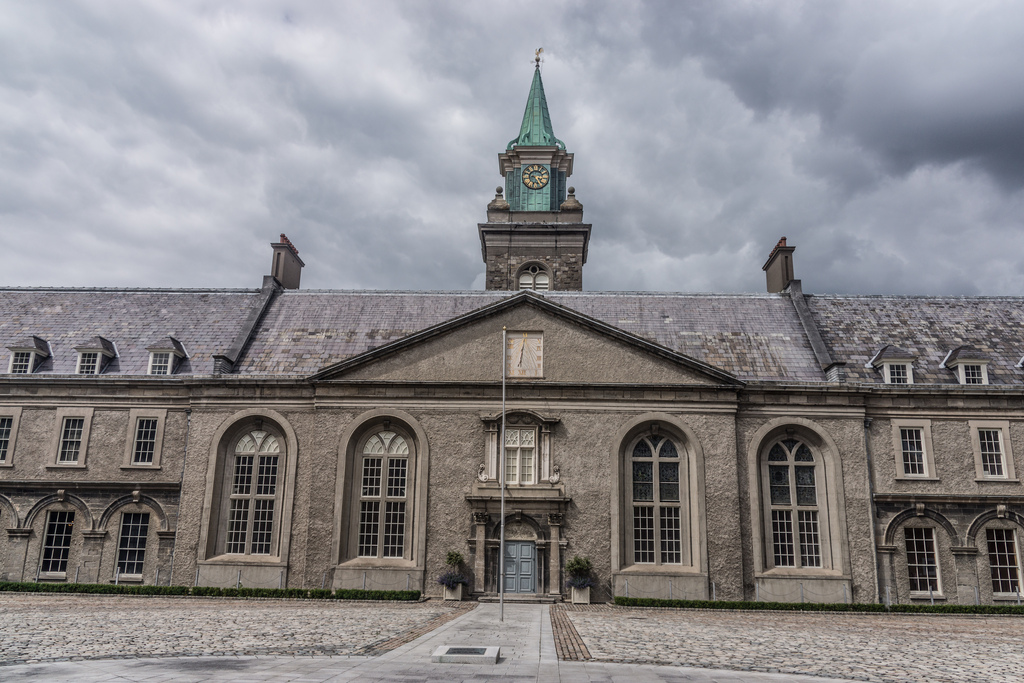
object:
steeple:
[477, 47, 592, 291]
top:
[506, 47, 567, 151]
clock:
[521, 164, 548, 190]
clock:
[503, 326, 547, 380]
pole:
[499, 326, 505, 622]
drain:
[432, 646, 501, 665]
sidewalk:
[0, 592, 1021, 683]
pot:
[438, 550, 470, 601]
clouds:
[0, 0, 1024, 298]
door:
[468, 509, 569, 604]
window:
[112, 512, 151, 579]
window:
[986, 529, 1021, 593]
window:
[978, 429, 1010, 479]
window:
[900, 426, 932, 477]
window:
[761, 434, 833, 571]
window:
[904, 526, 943, 596]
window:
[55, 416, 85, 466]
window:
[131, 418, 158, 466]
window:
[41, 510, 76, 573]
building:
[0, 47, 1024, 617]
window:
[958, 363, 990, 385]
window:
[147, 352, 175, 375]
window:
[76, 351, 104, 375]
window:
[6, 351, 34, 374]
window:
[347, 423, 416, 560]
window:
[216, 421, 288, 555]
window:
[863, 346, 915, 385]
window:
[611, 412, 709, 578]